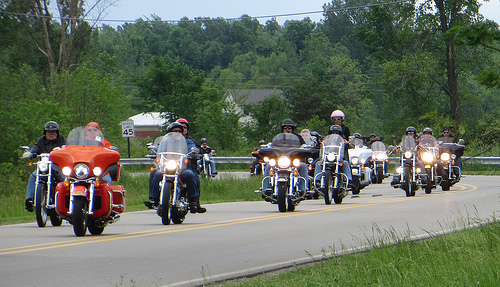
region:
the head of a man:
[38, 119, 60, 144]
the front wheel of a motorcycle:
[63, 189, 92, 242]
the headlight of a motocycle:
[72, 160, 88, 177]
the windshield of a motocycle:
[158, 132, 188, 152]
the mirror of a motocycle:
[188, 143, 200, 158]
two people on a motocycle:
[145, 118, 210, 228]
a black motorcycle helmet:
[278, 116, 295, 128]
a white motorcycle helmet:
[327, 108, 345, 118]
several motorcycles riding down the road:
[20, 97, 485, 239]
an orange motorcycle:
[54, 119, 124, 235]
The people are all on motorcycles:
[15, 65, 492, 237]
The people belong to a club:
[0, 51, 485, 241]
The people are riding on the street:
[0, 26, 496, 276]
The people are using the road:
[10, 30, 490, 256]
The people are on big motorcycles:
[0, 62, 485, 264]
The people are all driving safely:
[5, 70, 483, 270]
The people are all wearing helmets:
[140, 50, 485, 272]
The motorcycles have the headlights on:
[126, 75, 496, 256]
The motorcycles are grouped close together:
[122, 73, 497, 270]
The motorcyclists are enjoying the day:
[135, 40, 499, 248]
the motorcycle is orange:
[39, 115, 128, 243]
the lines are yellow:
[111, 218, 157, 255]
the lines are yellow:
[38, 218, 113, 263]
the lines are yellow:
[0, 217, 126, 284]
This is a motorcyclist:
[155, 116, 203, 236]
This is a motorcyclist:
[55, 121, 116, 235]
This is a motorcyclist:
[17, 106, 72, 227]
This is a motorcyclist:
[268, 112, 300, 220]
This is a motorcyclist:
[322, 111, 356, 206]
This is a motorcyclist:
[351, 123, 369, 197]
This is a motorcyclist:
[365, 128, 390, 185]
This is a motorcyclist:
[398, 112, 418, 190]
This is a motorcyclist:
[418, 123, 442, 185]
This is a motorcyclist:
[440, 123, 462, 191]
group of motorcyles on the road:
[16, 63, 498, 238]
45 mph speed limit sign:
[116, 118, 138, 156]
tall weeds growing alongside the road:
[326, 215, 499, 285]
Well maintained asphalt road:
[218, 223, 328, 253]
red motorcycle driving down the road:
[48, 114, 130, 240]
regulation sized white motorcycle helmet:
[328, 105, 345, 119]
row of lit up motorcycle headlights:
[261, 150, 311, 169]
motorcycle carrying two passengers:
[142, 113, 211, 230]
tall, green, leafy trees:
[116, 20, 452, 98]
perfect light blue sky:
[135, 3, 282, 17]